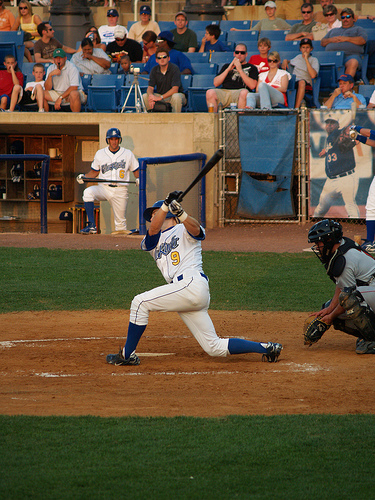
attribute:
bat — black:
[173, 149, 224, 204]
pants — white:
[116, 271, 233, 352]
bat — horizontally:
[66, 173, 132, 193]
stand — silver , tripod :
[120, 79, 149, 111]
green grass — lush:
[0, 414, 373, 499]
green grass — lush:
[2, 246, 342, 308]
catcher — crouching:
[300, 215, 374, 354]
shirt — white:
[146, 230, 204, 278]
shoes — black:
[102, 348, 155, 371]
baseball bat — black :
[173, 146, 226, 201]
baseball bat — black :
[80, 173, 143, 188]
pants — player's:
[125, 272, 230, 351]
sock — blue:
[226, 338, 262, 351]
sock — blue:
[125, 320, 143, 358]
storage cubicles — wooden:
[0, 132, 75, 203]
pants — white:
[112, 275, 232, 345]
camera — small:
[130, 65, 140, 74]